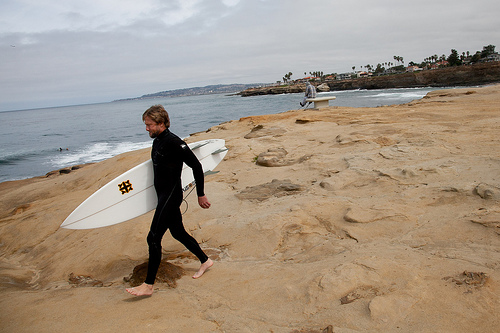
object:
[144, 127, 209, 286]
swimsuit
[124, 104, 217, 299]
man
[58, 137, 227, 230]
surfboard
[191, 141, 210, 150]
fin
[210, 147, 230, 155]
fin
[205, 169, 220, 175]
fin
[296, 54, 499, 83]
buildings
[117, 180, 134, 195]
logo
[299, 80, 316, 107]
jumper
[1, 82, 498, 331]
ground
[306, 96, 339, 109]
bench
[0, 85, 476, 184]
water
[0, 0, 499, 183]
background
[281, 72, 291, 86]
tree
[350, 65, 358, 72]
tree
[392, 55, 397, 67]
tree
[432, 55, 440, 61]
tree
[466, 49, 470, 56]
tree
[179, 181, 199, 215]
cord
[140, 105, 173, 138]
head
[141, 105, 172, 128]
hair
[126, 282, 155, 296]
foot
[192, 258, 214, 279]
foot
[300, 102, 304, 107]
foot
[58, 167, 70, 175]
rock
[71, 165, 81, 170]
rock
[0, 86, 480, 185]
coast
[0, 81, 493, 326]
beach